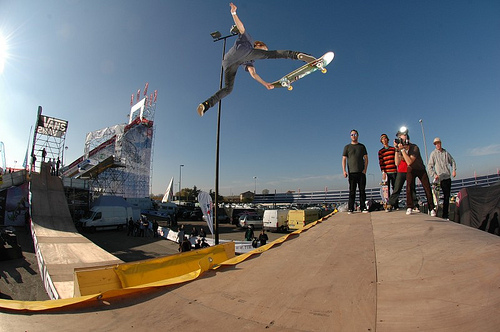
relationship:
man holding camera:
[196, 2, 316, 116] [393, 137, 402, 145]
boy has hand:
[341, 129, 368, 215] [361, 172, 365, 175]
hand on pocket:
[361, 172, 365, 175] [359, 172, 369, 174]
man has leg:
[209, 30, 282, 85] [193, 66, 238, 116]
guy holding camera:
[425, 136, 456, 221] [393, 137, 406, 149]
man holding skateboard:
[196, 2, 316, 116] [265, 51, 335, 92]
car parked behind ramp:
[235, 211, 263, 228] [13, 199, 493, 322]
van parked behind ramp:
[262, 208, 289, 233] [13, 199, 493, 322]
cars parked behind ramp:
[285, 208, 327, 229] [13, 199, 493, 322]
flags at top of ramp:
[124, 82, 159, 124] [24, 112, 155, 223]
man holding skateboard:
[196, 2, 316, 116] [265, 47, 338, 90]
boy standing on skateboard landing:
[376, 133, 401, 211] [0, 205, 497, 330]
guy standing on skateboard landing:
[425, 136, 456, 221] [0, 205, 497, 330]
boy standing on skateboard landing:
[398, 126, 438, 216] [0, 205, 497, 330]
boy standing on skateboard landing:
[338, 129, 370, 216] [0, 205, 497, 330]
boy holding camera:
[341, 129, 368, 215] [392, 137, 402, 150]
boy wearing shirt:
[341, 129, 368, 215] [341, 141, 367, 173]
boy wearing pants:
[341, 129, 368, 215] [342, 167, 368, 213]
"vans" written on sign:
[41, 114, 65, 132] [37, 115, 69, 135]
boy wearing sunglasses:
[341, 129, 368, 215] [343, 127, 362, 140]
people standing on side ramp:
[24, 145, 66, 179] [5, 171, 240, 308]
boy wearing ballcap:
[341, 129, 368, 215] [431, 137, 440, 143]